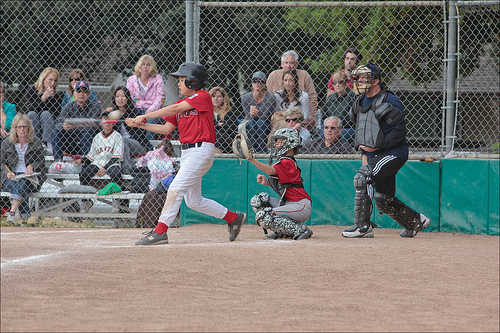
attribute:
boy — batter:
[120, 56, 251, 253]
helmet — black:
[166, 54, 216, 99]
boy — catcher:
[226, 115, 328, 247]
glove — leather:
[229, 121, 260, 171]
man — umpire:
[338, 45, 437, 247]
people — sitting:
[0, 38, 412, 166]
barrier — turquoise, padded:
[164, 151, 500, 238]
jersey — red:
[159, 88, 222, 154]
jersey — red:
[268, 153, 316, 205]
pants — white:
[152, 137, 234, 232]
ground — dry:
[0, 222, 499, 332]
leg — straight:
[148, 147, 206, 242]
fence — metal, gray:
[1, 1, 499, 230]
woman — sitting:
[235, 64, 279, 154]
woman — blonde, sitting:
[1, 108, 52, 232]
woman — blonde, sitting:
[19, 61, 70, 162]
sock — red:
[217, 201, 242, 228]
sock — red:
[150, 211, 175, 239]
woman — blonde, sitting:
[119, 42, 170, 142]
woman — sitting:
[202, 82, 241, 160]